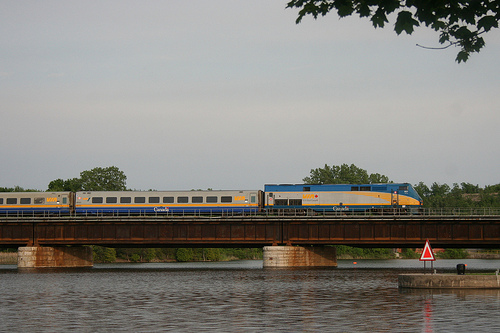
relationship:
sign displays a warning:
[420, 241, 437, 275] [419, 237, 434, 260]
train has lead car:
[3, 181, 429, 211] [267, 183, 425, 208]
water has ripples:
[156, 278, 364, 320] [233, 293, 385, 312]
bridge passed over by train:
[9, 220, 485, 262] [3, 181, 429, 211]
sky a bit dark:
[0, 0, 499, 192] [208, 59, 344, 137]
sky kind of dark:
[136, 32, 308, 152] [208, 59, 344, 137]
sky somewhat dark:
[0, 0, 499, 192] [208, 59, 344, 137]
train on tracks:
[3, 181, 429, 211] [2, 214, 497, 228]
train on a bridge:
[3, 181, 429, 211] [9, 220, 485, 262]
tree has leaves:
[295, 1, 499, 66] [294, 2, 489, 38]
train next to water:
[3, 181, 429, 211] [156, 278, 364, 320]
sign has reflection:
[420, 241, 437, 275] [422, 291, 438, 329]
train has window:
[3, 181, 429, 211] [398, 183, 411, 193]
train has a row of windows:
[3, 181, 429, 211] [89, 195, 235, 207]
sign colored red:
[420, 241, 437, 275] [419, 245, 434, 263]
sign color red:
[420, 241, 437, 275] [419, 245, 434, 263]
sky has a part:
[136, 32, 308, 152] [201, 33, 289, 136]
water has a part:
[156, 278, 364, 320] [214, 276, 252, 324]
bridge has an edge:
[9, 220, 485, 262] [4, 216, 494, 224]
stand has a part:
[263, 242, 338, 271] [288, 245, 310, 271]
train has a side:
[3, 181, 429, 211] [9, 192, 408, 202]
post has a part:
[420, 241, 437, 275] [420, 247, 429, 267]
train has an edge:
[3, 181, 429, 211] [3, 185, 415, 194]